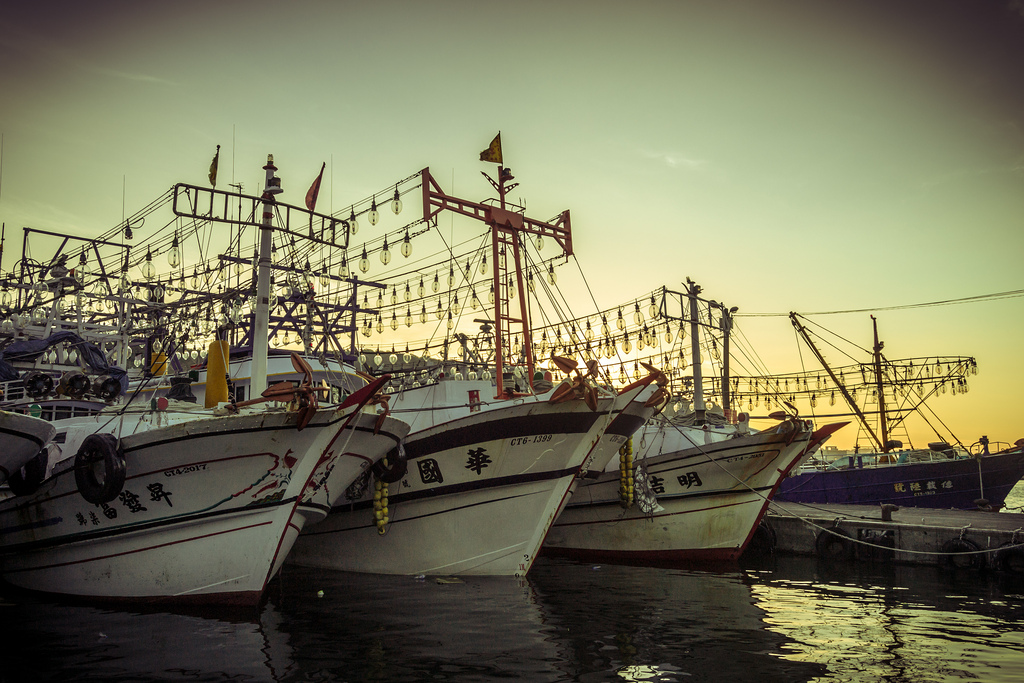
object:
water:
[780, 538, 961, 667]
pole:
[681, 282, 705, 416]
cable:
[725, 310, 974, 462]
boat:
[0, 141, 410, 621]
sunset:
[509, 311, 978, 452]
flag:
[480, 131, 502, 166]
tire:
[369, 444, 406, 482]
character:
[463, 447, 493, 476]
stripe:
[361, 454, 589, 527]